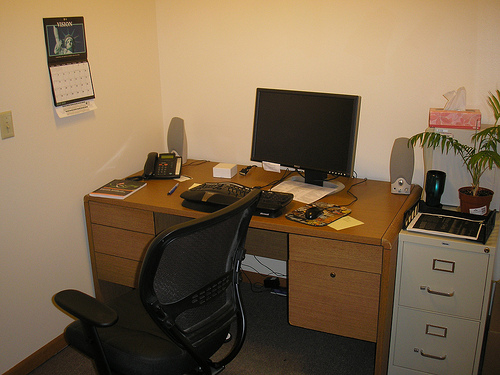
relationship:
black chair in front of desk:
[53, 186, 264, 374] [80, 150, 420, 371]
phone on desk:
[146, 147, 182, 181] [77, 158, 417, 348]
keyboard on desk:
[179, 183, 294, 218] [77, 158, 417, 348]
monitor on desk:
[245, 84, 359, 198] [80, 150, 420, 371]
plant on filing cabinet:
[404, 83, 498, 216] [384, 191, 498, 372]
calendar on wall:
[38, 14, 102, 129] [1, 1, 164, 372]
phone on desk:
[143, 150, 182, 181] [80, 150, 420, 371]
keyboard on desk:
[179, 183, 294, 218] [80, 150, 420, 371]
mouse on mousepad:
[306, 206, 324, 219] [285, 196, 353, 228]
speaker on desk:
[167, 115, 185, 163] [80, 150, 420, 371]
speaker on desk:
[162, 115, 194, 163] [80, 150, 420, 371]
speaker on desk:
[386, 137, 415, 196] [80, 150, 420, 371]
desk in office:
[80, 150, 420, 371] [2, 3, 498, 373]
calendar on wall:
[41, 17, 101, 120] [1, 1, 164, 372]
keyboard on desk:
[182, 183, 290, 216] [80, 150, 420, 371]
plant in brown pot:
[404, 88, 499, 200] [459, 175, 485, 219]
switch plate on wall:
[3, 110, 25, 154] [33, 150, 65, 212]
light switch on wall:
[1, 111, 15, 140] [30, 152, 38, 189]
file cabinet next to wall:
[404, 235, 473, 370] [404, 79, 468, 144]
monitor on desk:
[248, 87, 360, 179] [323, 200, 388, 294]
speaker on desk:
[393, 132, 441, 209] [345, 183, 390, 258]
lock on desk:
[308, 265, 380, 327] [173, 152, 340, 219]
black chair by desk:
[160, 220, 273, 326] [191, 120, 351, 235]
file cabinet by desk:
[398, 241, 490, 321] [413, 224, 485, 366]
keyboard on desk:
[179, 183, 294, 218] [185, 148, 448, 278]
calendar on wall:
[41, 17, 101, 120] [15, 4, 135, 164]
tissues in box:
[442, 83, 471, 110] [424, 104, 480, 129]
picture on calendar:
[50, 17, 80, 58] [38, 14, 102, 129]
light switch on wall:
[1, 106, 19, 138] [1, 50, 48, 191]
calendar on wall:
[41, 17, 101, 120] [6, 0, 147, 161]